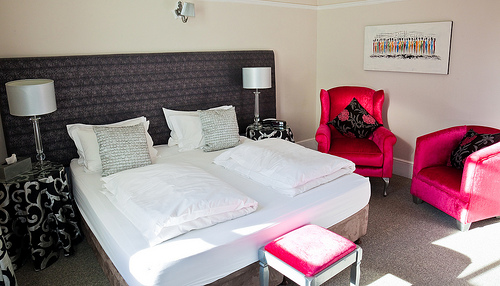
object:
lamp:
[242, 66, 273, 130]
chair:
[313, 85, 397, 199]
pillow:
[325, 97, 383, 139]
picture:
[362, 20, 453, 74]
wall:
[317, 0, 499, 179]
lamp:
[4, 78, 59, 167]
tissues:
[5, 153, 18, 165]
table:
[0, 160, 65, 249]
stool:
[256, 222, 364, 286]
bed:
[69, 134, 371, 286]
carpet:
[0, 223, 115, 286]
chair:
[410, 123, 500, 232]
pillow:
[449, 126, 500, 170]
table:
[247, 122, 290, 143]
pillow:
[92, 121, 154, 177]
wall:
[0, 2, 317, 160]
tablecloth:
[246, 123, 296, 143]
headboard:
[0, 49, 277, 168]